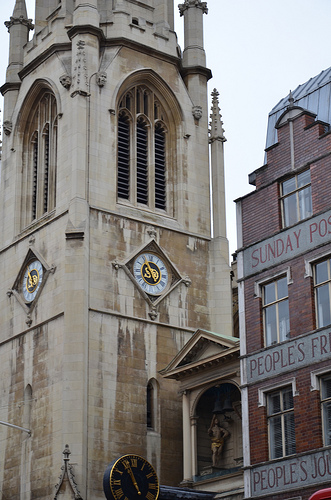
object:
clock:
[125, 237, 183, 308]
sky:
[203, 4, 330, 270]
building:
[236, 59, 331, 500]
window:
[278, 164, 313, 229]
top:
[232, 65, 330, 234]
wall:
[291, 374, 323, 452]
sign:
[243, 448, 330, 500]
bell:
[211, 386, 235, 413]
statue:
[207, 414, 229, 466]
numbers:
[137, 261, 145, 283]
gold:
[143, 254, 156, 282]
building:
[0, 0, 238, 500]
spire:
[208, 86, 233, 343]